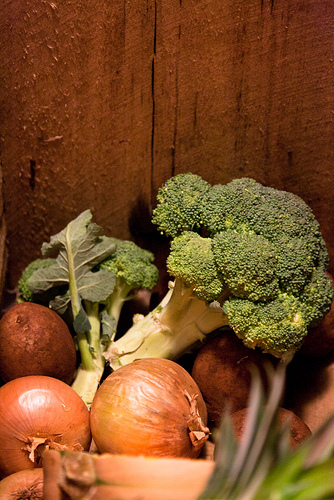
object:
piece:
[167, 220, 312, 355]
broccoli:
[103, 174, 334, 370]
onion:
[88, 357, 213, 456]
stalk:
[110, 282, 239, 373]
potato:
[0, 301, 77, 390]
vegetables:
[0, 170, 334, 499]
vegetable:
[17, 208, 159, 409]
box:
[0, 0, 334, 316]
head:
[152, 175, 334, 365]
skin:
[113, 389, 176, 427]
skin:
[16, 301, 41, 351]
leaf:
[25, 207, 117, 334]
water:
[129, 366, 155, 381]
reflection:
[122, 382, 154, 414]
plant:
[0, 0, 334, 315]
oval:
[29, 155, 39, 189]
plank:
[0, 0, 334, 306]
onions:
[0, 357, 207, 475]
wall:
[0, 0, 334, 303]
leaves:
[197, 428, 334, 499]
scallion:
[222, 355, 292, 499]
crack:
[150, 1, 159, 204]